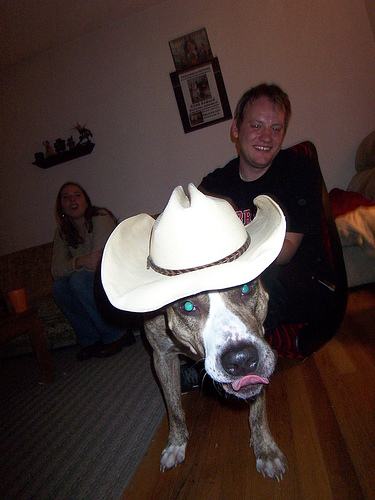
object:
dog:
[144, 275, 289, 483]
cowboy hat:
[100, 182, 287, 314]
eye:
[184, 300, 194, 312]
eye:
[241, 284, 252, 295]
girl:
[51, 182, 136, 360]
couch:
[1, 213, 161, 355]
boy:
[196, 82, 322, 327]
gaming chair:
[264, 141, 348, 360]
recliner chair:
[324, 130, 374, 289]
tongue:
[231, 375, 270, 392]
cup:
[8, 287, 29, 315]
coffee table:
[1, 303, 53, 381]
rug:
[0, 331, 167, 500]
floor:
[122, 284, 375, 498]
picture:
[187, 72, 212, 104]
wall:
[1, 0, 375, 258]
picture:
[168, 27, 213, 73]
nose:
[221, 340, 260, 377]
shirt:
[199, 155, 319, 328]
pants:
[50, 271, 129, 346]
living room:
[1, 0, 373, 499]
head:
[153, 230, 278, 401]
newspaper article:
[170, 56, 234, 134]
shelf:
[31, 140, 96, 169]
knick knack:
[69, 120, 93, 145]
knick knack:
[66, 135, 75, 150]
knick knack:
[53, 137, 66, 154]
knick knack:
[42, 140, 56, 158]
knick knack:
[34, 152, 45, 162]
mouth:
[222, 375, 270, 393]